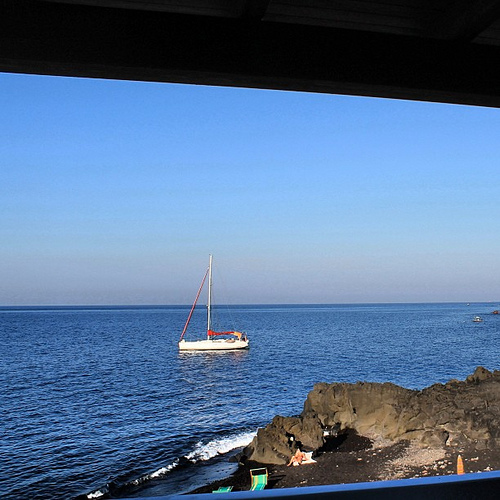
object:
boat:
[171, 251, 248, 365]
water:
[0, 298, 499, 499]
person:
[285, 441, 302, 467]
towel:
[289, 449, 316, 470]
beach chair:
[242, 460, 269, 492]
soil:
[224, 460, 416, 495]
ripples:
[0, 303, 499, 499]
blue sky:
[1, 72, 498, 302]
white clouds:
[0, 69, 498, 306]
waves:
[0, 304, 499, 499]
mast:
[181, 253, 221, 333]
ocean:
[0, 302, 499, 496]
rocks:
[239, 364, 499, 498]